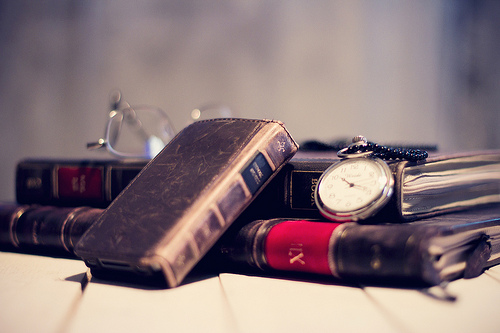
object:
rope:
[348, 143, 429, 160]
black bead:
[415, 154, 419, 159]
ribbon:
[463, 232, 492, 279]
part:
[135, 233, 207, 305]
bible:
[73, 118, 301, 289]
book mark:
[465, 231, 492, 278]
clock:
[314, 156, 395, 221]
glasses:
[116, 114, 164, 152]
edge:
[0, 205, 429, 283]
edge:
[160, 122, 299, 289]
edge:
[14, 157, 406, 221]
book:
[15, 149, 498, 221]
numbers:
[341, 168, 346, 172]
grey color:
[407, 3, 470, 97]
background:
[0, 1, 500, 153]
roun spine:
[0, 206, 427, 288]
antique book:
[1, 184, 498, 290]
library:
[0, 117, 498, 290]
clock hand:
[353, 185, 366, 187]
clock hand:
[342, 178, 351, 184]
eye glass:
[86, 105, 255, 156]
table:
[0, 244, 500, 333]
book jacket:
[0, 202, 499, 293]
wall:
[0, 1, 500, 156]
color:
[324, 171, 381, 196]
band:
[347, 144, 428, 160]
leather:
[139, 180, 175, 223]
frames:
[104, 104, 180, 159]